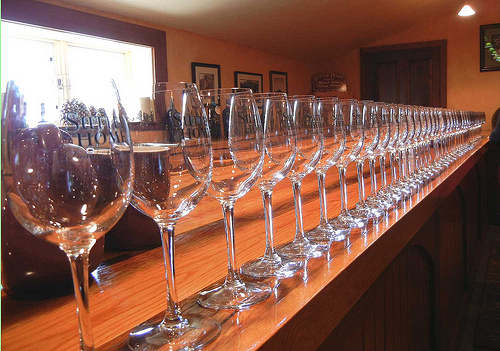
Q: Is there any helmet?
A: No, there are no helmets.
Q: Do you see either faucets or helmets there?
A: No, there are no helmets or faucets.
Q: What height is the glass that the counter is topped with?
A: The glass is tall.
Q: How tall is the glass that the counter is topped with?
A: The glass is tall.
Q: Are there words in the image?
A: Yes, there are words.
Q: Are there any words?
A: Yes, there are words.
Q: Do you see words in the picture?
A: Yes, there are words.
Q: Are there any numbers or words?
A: Yes, there are words.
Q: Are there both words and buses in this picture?
A: No, there are words but no buses.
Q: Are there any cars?
A: No, there are no cars.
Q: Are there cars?
A: No, there are no cars.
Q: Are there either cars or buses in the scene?
A: No, there are no cars or buses.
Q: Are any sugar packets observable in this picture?
A: No, there are no sugar packets.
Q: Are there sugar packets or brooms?
A: No, there are no sugar packets or brooms.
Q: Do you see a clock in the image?
A: No, there are no clocks.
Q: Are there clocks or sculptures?
A: No, there are no clocks or sculptures.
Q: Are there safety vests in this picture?
A: No, there are no safety vests.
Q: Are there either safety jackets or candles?
A: No, there are no safety jackets or candles.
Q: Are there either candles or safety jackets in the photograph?
A: No, there are no safety jackets or candles.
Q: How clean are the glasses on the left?
A: The glasses are clean.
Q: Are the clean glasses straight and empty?
A: Yes, the glasses are straight and empty.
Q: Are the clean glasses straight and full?
A: No, the glasses are straight but empty.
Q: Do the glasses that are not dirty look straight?
A: Yes, the glasses are straight.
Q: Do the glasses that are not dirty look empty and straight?
A: Yes, the glasses are empty and straight.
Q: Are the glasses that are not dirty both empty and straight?
A: Yes, the glasses are empty and straight.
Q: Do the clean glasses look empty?
A: Yes, the glasses are empty.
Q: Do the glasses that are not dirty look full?
A: No, the glasses are empty.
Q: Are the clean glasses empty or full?
A: The glasses are empty.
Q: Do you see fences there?
A: No, there are no fences.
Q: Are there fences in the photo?
A: No, there are no fences.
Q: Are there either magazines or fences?
A: No, there are no fences or magazines.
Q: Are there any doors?
A: Yes, there is a door.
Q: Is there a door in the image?
A: Yes, there is a door.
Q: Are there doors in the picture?
A: Yes, there is a door.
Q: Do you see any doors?
A: Yes, there is a door.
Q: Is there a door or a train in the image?
A: Yes, there is a door.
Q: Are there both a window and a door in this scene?
A: Yes, there are both a door and a window.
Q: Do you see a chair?
A: No, there are no chairs.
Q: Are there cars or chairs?
A: No, there are no chairs or cars.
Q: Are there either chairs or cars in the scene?
A: No, there are no chairs or cars.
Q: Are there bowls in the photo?
A: No, there are no bowls.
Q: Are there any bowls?
A: No, there are no bowls.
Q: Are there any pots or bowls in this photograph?
A: No, there are no bowls or pots.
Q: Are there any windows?
A: Yes, there is a window.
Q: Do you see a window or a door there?
A: Yes, there is a window.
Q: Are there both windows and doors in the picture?
A: Yes, there are both a window and a door.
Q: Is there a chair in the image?
A: No, there are no chairs.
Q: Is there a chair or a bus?
A: No, there are no chairs or buses.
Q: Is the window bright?
A: Yes, the window is bright.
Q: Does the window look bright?
A: Yes, the window is bright.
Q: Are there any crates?
A: No, there are no crates.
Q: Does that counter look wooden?
A: Yes, the counter is wooden.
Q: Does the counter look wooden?
A: Yes, the counter is wooden.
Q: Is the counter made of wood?
A: Yes, the counter is made of wood.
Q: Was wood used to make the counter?
A: Yes, the counter is made of wood.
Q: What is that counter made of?
A: The counter is made of wood.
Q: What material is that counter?
A: The counter is made of wood.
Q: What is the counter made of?
A: The counter is made of wood.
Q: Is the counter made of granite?
A: No, the counter is made of wood.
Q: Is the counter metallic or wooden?
A: The counter is wooden.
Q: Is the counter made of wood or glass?
A: The counter is made of wood.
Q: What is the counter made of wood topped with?
A: The counter is topped with glass.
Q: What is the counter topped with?
A: The counter is topped with glass.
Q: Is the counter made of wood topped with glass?
A: Yes, the counter is topped with glass.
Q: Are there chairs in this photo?
A: No, there are no chairs.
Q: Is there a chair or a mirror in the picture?
A: No, there are no chairs or mirrors.